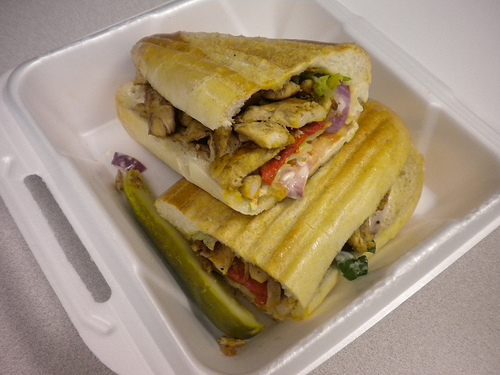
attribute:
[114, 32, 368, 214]
sandwich — layered, cut, in the box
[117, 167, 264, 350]
pickle — colored green, green, dill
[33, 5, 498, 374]
box — white, foam, open, styrofoam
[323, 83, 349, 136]
food — purple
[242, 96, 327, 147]
meat — chicken breast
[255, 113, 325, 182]
pepper — red, cooked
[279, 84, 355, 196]
onion — cooked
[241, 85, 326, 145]
chicken — grilled